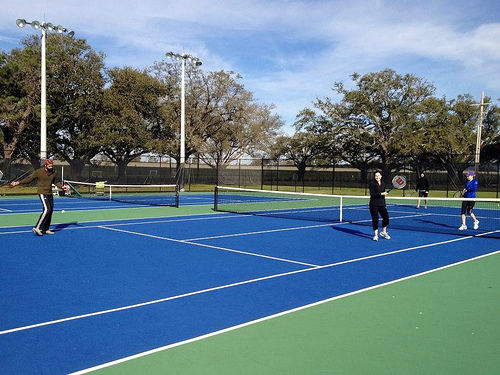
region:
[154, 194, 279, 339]
the line is white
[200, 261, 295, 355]
the line is white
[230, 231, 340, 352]
the line is white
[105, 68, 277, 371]
the line is white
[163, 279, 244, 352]
the line is white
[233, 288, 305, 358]
the line is white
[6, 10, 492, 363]
A tennis court scene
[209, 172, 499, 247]
A net is in the middle of the court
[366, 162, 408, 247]
This woman is holding a tennis racket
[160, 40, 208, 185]
A light post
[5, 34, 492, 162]
Trees are growing outside the court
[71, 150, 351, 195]
A fence surrounds the tennis court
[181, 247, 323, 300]
The in bounds area is blue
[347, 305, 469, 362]
The out of bounds area is green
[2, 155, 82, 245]
This man is swinging at the tennis ball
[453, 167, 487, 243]
This person is standing near the net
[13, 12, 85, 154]
lighting for tennis courts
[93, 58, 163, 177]
green tree beside tennis courts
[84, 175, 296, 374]
blue, green and white tennis courts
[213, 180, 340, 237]
tennis court net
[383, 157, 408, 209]
black and white tennis racket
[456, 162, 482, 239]
lady in blue top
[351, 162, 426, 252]
lady with tennis racket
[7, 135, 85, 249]
man playing tennis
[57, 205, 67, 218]
tennis ball in the air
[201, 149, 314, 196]
fence around tennis court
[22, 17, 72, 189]
lights on top of tall silver pole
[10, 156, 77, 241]
man swinging tennis raquet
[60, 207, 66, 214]
green tennis ball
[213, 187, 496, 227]
net on blue tennis court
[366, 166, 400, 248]
woman in all black outfit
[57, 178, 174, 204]
black and white tennis net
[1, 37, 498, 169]
trees in the park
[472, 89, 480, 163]
wooden telephone pole behind courts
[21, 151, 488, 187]
black fencing behind tennis courts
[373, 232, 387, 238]
white sneakers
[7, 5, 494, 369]
four people playing tennis on a tennis court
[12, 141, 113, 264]
man wearing black and white jogging pants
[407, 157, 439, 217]
man wearing black shorts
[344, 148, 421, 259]
woman wearing black athletic capri pants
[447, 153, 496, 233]
woman wearing black athletic capri pants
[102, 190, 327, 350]
blue and green tennis court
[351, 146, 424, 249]
woman holding a tennis racket with a W on it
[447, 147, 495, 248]
woman wearing a royal blue pullover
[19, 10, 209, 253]
two light posts on a tennis court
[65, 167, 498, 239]
two tennis nets stretched across a tennis court